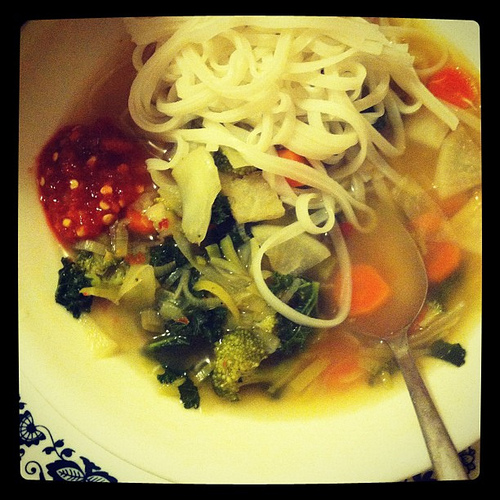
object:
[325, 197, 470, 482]
spoon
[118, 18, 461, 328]
noodles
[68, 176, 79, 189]
seed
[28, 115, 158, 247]
sauce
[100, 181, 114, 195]
seed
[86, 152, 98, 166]
seed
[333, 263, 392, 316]
carrot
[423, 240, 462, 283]
carrot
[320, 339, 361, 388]
carrot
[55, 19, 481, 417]
vegetable soup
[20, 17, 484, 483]
bowl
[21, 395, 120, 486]
design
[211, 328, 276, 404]
broccoli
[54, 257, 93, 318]
kale